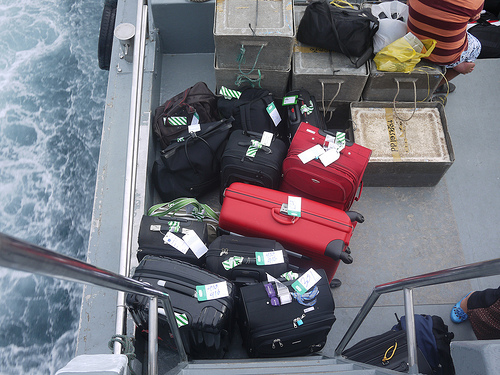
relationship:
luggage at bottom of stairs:
[234, 269, 341, 353] [0, 227, 499, 372]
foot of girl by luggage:
[452, 59, 476, 76] [362, 58, 444, 102]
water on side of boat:
[1, 1, 108, 375] [1, 2, 496, 374]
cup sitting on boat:
[112, 22, 135, 63] [1, 2, 496, 374]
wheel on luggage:
[329, 239, 356, 266] [216, 179, 365, 289]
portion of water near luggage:
[112, 22, 135, 63] [154, 80, 213, 141]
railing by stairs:
[4, 214, 500, 375] [0, 227, 499, 372]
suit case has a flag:
[219, 126, 286, 202] [247, 140, 260, 158]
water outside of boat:
[1, 1, 108, 375] [1, 2, 496, 374]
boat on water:
[1, 2, 496, 374] [1, 1, 108, 375]